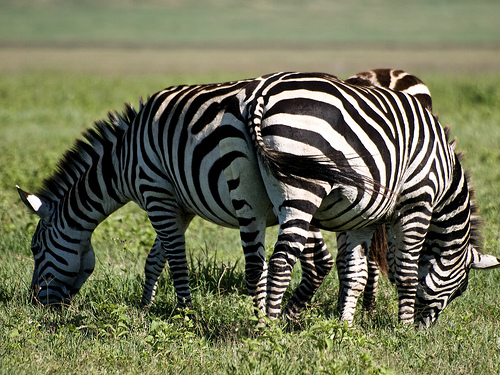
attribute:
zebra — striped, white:
[35, 94, 272, 308]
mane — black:
[34, 113, 141, 194]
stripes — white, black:
[469, 245, 481, 264]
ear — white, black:
[20, 183, 54, 223]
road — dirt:
[3, 36, 498, 78]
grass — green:
[43, 20, 490, 61]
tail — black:
[240, 127, 388, 202]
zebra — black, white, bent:
[29, 72, 440, 373]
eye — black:
[31, 241, 46, 255]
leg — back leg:
[252, 99, 307, 334]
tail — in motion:
[244, 95, 399, 200]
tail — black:
[239, 90, 379, 204]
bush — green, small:
[454, 75, 484, 105]